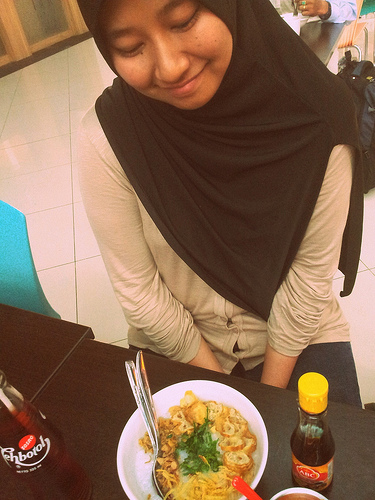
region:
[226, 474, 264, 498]
handle of red silverware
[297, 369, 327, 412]
yellow cap of a condiment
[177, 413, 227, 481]
green garnish in a bowl of food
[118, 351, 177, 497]
silverware in the bowl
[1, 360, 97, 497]
an soda on the table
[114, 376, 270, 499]
a white bowl of food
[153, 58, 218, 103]
a person's smile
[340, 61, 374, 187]
a blue backpack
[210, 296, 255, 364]
buttons on a brown shirt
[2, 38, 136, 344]
white tiled wall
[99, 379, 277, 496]
A bowl of food with two spoons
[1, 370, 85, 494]
A bottle of soda on a bottle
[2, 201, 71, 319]
A blue chair that is empty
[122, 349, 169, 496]
Two spoons in a bowl of food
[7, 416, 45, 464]
A red circle on a bottle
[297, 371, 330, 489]
A bottle with a yellow cap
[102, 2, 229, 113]
The girl is smiling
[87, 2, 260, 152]
Girl is wearing a burka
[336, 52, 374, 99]
The handle on a backpack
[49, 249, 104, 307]
The tile on the floor is tan in color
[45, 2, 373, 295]
girl wearing black cover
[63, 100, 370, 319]
girl's shirt is brown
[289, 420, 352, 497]
the bottle is brown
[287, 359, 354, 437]
bottle's top is yellow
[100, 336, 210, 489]
silver spoon in the bowl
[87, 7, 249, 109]
the girl is smiling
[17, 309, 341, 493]
the table is black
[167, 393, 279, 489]
yellow food in bowl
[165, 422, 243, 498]
green food in center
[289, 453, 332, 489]
red label on bottle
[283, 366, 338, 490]
bottle of sauce on a table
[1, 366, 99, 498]
glass bottle with liquid inside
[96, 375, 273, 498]
bowl with food inside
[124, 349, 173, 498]
silver metal spoon inside a bowl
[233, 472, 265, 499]
handle of a plastic spoon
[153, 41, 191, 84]
nose of a person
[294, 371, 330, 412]
yellow plastic lid of a bottle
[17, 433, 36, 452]
red logo on a bottle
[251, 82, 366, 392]
arm of a person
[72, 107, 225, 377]
arm of a person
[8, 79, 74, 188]
White tiles on the ground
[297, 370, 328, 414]
A yellow bottle top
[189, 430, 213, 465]
Green vegetables on a plate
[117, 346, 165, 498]
Cuttler sticking out of a plate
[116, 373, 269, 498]
A white plate on a table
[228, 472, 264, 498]
A reddish spoon handle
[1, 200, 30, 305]
The blue back rest of a chair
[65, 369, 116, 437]
A brownish bottle top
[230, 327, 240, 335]
A brown sweater button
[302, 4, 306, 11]
A golden finger ring